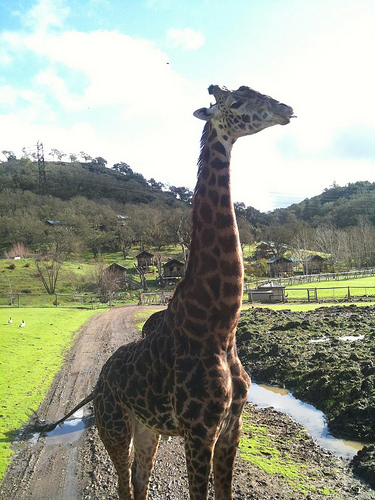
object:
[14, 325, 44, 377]
grass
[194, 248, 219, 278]
spot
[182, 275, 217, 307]
spot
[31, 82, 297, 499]
giraffe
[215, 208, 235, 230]
spot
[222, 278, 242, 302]
spot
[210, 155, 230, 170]
spot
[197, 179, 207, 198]
spot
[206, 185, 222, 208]
spot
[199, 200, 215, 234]
spot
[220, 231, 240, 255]
spot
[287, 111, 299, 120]
tongue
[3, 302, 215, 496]
road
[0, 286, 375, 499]
field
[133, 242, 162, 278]
building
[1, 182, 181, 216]
hillside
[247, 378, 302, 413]
water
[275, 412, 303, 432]
mud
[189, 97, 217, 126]
horns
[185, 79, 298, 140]
head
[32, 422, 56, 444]
hairs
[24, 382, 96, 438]
tail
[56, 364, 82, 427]
tracks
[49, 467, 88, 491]
mud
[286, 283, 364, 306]
fence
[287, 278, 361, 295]
pen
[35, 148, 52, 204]
pole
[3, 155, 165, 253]
hill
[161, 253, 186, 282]
buildings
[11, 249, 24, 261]
animals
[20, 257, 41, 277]
grass